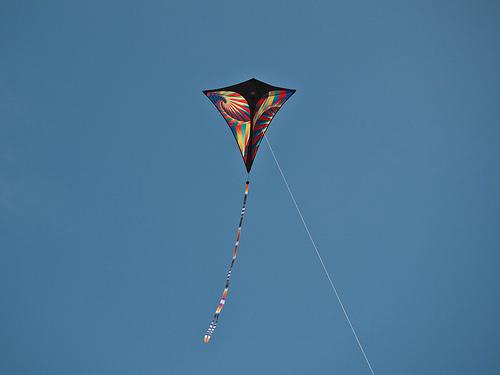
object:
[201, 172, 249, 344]
tail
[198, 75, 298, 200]
kite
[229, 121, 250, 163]
stripe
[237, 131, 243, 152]
orange design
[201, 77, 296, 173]
diamond shape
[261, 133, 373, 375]
string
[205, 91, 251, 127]
print